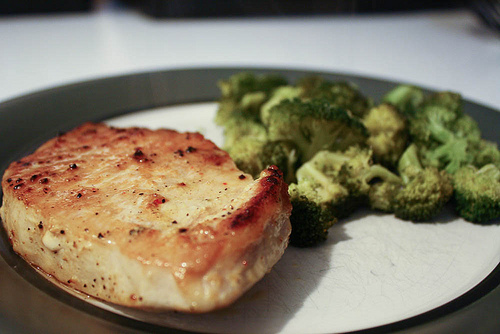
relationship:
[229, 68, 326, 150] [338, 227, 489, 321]
veggies on plate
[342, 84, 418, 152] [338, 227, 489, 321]
veggies on plate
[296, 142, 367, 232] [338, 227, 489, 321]
veggies on plate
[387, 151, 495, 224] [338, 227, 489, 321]
veggies on plate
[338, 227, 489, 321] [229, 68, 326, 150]
plate has veggies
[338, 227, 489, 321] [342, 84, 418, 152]
plate has veggies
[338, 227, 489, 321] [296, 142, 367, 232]
plate has veggies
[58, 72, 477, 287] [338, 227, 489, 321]
food on plate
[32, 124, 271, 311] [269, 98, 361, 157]
fish with broccoli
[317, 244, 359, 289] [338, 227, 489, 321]
marks on plate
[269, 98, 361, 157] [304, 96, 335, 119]
broccoli has florets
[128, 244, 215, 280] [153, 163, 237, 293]
moisture on meat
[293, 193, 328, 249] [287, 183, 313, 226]
crown of floret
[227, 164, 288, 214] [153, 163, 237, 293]
marks on meat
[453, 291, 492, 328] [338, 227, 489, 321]
rim on plate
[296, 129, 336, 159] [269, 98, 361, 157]
stem of broccoli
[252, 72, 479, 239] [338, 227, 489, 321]
food on plate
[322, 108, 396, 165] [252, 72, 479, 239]
green on food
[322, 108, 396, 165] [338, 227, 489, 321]
green on plate